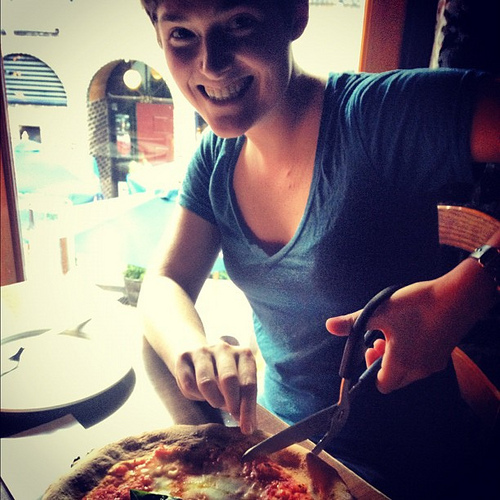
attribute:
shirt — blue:
[173, 78, 451, 445]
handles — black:
[339, 283, 399, 396]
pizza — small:
[83, 437, 342, 497]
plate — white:
[8, 314, 165, 424]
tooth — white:
[224, 89, 229, 98]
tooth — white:
[225, 85, 242, 97]